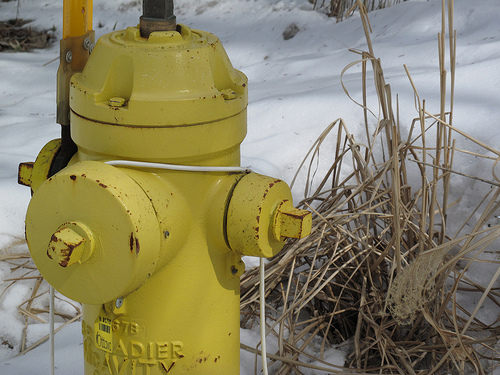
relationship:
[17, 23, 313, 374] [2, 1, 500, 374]
fire hydrant located in snow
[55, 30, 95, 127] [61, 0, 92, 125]
panel mounted on pole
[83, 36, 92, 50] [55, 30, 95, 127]
screw attached to panel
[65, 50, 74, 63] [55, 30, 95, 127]
screw attached to panel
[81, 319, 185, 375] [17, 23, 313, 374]
lettering visible on fire hydrant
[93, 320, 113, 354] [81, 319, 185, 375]
sticker over lettering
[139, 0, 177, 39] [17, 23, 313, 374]
plug on top of fire hydrant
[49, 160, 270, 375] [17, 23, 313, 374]
cord stretched across fire hydrant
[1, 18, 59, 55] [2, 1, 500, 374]
debris on top of snow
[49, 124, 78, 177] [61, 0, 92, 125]
base of pole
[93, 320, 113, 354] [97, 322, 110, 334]
sticker has bar code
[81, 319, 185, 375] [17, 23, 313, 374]
lettering on side of fire hydrant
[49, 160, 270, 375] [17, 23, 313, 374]
cord stretched over fire hydrant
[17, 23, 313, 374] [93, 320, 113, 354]
fire hydrant has sticker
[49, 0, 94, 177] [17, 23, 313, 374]
wrench on side of fire hydrant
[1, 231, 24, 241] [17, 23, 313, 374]
grass next to fire hydrant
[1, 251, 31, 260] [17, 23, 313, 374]
grass next to fire hydrant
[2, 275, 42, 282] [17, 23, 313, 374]
grass next to fire hydrant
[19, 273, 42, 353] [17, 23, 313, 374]
grass next to fire hydrant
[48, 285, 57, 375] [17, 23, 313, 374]
grass next to fire hydrant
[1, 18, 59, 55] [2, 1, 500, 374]
debris laying in snow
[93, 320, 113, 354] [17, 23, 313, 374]
sticker on side of fire hydrant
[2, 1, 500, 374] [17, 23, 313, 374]
snow gathered around fire hydrant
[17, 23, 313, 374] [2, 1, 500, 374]
fire hydrant next to snow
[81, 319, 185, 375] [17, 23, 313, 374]
lettering imprinted on fire hydrant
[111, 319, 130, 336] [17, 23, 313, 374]
numbers on side of fire hydrant